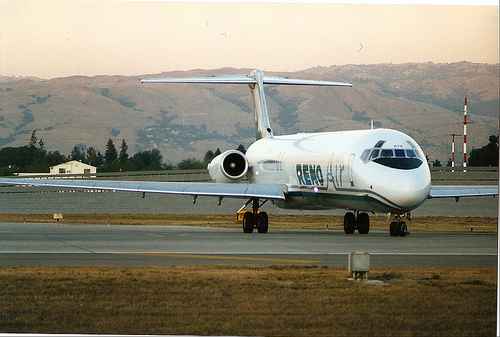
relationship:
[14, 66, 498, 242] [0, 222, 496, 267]
plane on tarmac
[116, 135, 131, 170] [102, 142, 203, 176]
tree in a field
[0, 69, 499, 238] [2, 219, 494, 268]
plane on tarmac